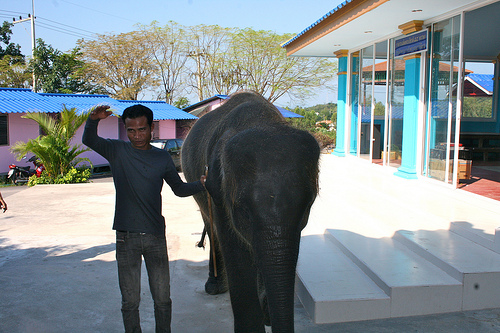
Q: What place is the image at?
A: It is at the pavement.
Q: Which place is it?
A: It is a pavement.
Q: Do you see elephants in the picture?
A: Yes, there is an elephant.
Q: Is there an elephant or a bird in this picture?
A: Yes, there is an elephant.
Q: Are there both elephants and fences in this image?
A: No, there is an elephant but no fences.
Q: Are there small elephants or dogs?
A: Yes, there is a small elephant.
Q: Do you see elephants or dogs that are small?
A: Yes, the elephant is small.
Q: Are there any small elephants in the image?
A: Yes, there is a small elephant.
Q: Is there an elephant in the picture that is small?
A: Yes, there is an elephant that is small.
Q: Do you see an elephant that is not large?
A: Yes, there is a small elephant.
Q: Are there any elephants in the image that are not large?
A: Yes, there is a small elephant.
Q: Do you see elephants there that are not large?
A: Yes, there is a small elephant.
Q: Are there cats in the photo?
A: No, there are no cats.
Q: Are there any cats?
A: No, there are no cats.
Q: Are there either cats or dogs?
A: No, there are no cats or dogs.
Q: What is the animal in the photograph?
A: The animal is an elephant.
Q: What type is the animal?
A: The animal is an elephant.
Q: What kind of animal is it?
A: The animal is an elephant.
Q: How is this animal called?
A: This is an elephant.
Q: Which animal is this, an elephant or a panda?
A: This is an elephant.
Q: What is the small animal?
A: The animal is an elephant.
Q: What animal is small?
A: The animal is an elephant.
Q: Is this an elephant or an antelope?
A: This is an elephant.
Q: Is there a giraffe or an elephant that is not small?
A: No, there is an elephant but it is small.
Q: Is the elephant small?
A: Yes, the elephant is small.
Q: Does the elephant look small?
A: Yes, the elephant is small.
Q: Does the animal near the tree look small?
A: Yes, the elephant is small.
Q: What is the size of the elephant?
A: The elephant is small.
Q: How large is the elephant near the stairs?
A: The elephant is small.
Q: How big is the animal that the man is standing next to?
A: The elephant is small.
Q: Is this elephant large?
A: No, the elephant is small.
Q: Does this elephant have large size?
A: No, the elephant is small.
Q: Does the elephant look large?
A: No, the elephant is small.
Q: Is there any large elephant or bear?
A: No, there is an elephant but it is small.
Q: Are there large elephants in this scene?
A: No, there is an elephant but it is small.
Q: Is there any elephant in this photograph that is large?
A: No, there is an elephant but it is small.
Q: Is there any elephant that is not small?
A: No, there is an elephant but it is small.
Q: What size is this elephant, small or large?
A: The elephant is small.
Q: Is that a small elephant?
A: Yes, that is a small elephant.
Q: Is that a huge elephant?
A: No, that is a small elephant.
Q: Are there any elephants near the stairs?
A: Yes, there is an elephant near the stairs.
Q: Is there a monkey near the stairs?
A: No, there is an elephant near the stairs.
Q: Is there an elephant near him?
A: Yes, there is an elephant near the man.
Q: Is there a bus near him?
A: No, there is an elephant near the man.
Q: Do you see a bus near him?
A: No, there is an elephant near the man.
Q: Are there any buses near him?
A: No, there is an elephant near the man.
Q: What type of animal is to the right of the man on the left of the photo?
A: The animal is an elephant.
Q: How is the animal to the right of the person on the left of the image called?
A: The animal is an elephant.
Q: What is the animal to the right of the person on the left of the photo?
A: The animal is an elephant.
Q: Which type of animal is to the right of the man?
A: The animal is an elephant.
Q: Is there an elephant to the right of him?
A: Yes, there is an elephant to the right of the man.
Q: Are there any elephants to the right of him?
A: Yes, there is an elephant to the right of the man.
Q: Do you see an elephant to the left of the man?
A: No, the elephant is to the right of the man.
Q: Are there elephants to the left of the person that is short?
A: No, the elephant is to the right of the man.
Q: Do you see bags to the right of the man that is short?
A: No, there is an elephant to the right of the man.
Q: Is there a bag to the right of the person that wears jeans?
A: No, there is an elephant to the right of the man.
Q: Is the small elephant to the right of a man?
A: Yes, the elephant is to the right of a man.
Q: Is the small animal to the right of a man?
A: Yes, the elephant is to the right of a man.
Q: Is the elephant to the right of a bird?
A: No, the elephant is to the right of a man.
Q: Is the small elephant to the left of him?
A: No, the elephant is to the right of the man.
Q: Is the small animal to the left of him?
A: No, the elephant is to the right of the man.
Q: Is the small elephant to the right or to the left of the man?
A: The elephant is to the right of the man.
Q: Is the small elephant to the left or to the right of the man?
A: The elephant is to the right of the man.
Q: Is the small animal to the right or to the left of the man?
A: The elephant is to the right of the man.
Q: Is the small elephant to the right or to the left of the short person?
A: The elephant is to the right of the man.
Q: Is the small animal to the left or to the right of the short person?
A: The elephant is to the right of the man.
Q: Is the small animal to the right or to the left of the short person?
A: The elephant is to the right of the man.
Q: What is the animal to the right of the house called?
A: The animal is an elephant.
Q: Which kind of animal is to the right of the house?
A: The animal is an elephant.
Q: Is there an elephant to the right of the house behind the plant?
A: Yes, there is an elephant to the right of the house.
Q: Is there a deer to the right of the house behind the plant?
A: No, there is an elephant to the right of the house.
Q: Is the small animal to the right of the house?
A: Yes, the elephant is to the right of the house.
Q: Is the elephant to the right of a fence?
A: No, the elephant is to the right of the house.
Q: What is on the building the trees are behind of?
A: The sign is on the building.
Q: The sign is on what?
A: The sign is on the building.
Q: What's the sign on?
A: The sign is on the building.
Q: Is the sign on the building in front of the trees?
A: Yes, the sign is on the building.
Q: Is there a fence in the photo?
A: No, there are no fences.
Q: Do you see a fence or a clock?
A: No, there are no fences or clocks.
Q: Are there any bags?
A: No, there are no bags.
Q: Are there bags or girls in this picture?
A: No, there are no bags or girls.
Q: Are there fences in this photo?
A: No, there are no fences.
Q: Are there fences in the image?
A: No, there are no fences.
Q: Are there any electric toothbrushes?
A: No, there are no electric toothbrushes.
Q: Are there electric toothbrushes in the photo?
A: No, there are no electric toothbrushes.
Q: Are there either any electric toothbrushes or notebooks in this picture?
A: No, there are no electric toothbrushes or notebooks.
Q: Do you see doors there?
A: Yes, there is a door.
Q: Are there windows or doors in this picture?
A: Yes, there is a door.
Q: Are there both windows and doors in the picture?
A: Yes, there are both a door and a window.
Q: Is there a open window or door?
A: Yes, there is an open door.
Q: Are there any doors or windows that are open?
A: Yes, the door is open.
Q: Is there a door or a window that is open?
A: Yes, the door is open.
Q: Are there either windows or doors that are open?
A: Yes, the door is open.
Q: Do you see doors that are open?
A: Yes, there is an open door.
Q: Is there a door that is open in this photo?
A: Yes, there is an open door.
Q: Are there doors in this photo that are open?
A: Yes, there is a door that is open.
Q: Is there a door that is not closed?
A: Yes, there is a open door.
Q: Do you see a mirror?
A: No, there are no mirrors.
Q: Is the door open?
A: Yes, the door is open.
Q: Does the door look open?
A: Yes, the door is open.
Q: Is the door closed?
A: No, the door is open.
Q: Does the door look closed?
A: No, the door is open.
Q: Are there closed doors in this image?
A: No, there is a door but it is open.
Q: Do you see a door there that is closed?
A: No, there is a door but it is open.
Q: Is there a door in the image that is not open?
A: No, there is a door but it is open.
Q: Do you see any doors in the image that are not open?
A: No, there is a door but it is open.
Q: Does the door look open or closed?
A: The door is open.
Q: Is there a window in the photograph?
A: Yes, there are windows.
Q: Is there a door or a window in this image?
A: Yes, there are windows.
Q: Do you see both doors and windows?
A: Yes, there are both windows and a door.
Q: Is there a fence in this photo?
A: No, there are no fences.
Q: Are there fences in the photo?
A: No, there are no fences.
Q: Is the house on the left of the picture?
A: Yes, the house is on the left of the image.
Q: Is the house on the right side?
A: No, the house is on the left of the image.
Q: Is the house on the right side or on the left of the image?
A: The house is on the left of the image.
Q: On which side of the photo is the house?
A: The house is on the left of the image.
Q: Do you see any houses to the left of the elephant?
A: Yes, there is a house to the left of the elephant.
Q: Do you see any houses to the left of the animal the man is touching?
A: Yes, there is a house to the left of the elephant.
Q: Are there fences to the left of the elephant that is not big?
A: No, there is a house to the left of the elephant.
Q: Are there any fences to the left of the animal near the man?
A: No, there is a house to the left of the elephant.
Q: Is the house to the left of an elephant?
A: Yes, the house is to the left of an elephant.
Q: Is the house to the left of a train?
A: No, the house is to the left of an elephant.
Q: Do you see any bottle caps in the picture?
A: No, there are no bottle caps.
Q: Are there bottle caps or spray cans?
A: No, there are no bottle caps or spray cans.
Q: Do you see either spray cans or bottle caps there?
A: No, there are no bottle caps or spray cans.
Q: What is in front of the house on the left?
A: The plant is in front of the house.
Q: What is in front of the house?
A: The plant is in front of the house.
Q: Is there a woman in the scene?
A: No, there are no women.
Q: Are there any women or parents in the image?
A: No, there are no women or parents.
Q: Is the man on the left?
A: Yes, the man is on the left of the image.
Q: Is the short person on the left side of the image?
A: Yes, the man is on the left of the image.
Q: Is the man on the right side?
A: No, the man is on the left of the image.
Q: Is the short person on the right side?
A: No, the man is on the left of the image.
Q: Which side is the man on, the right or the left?
A: The man is on the left of the image.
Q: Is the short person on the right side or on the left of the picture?
A: The man is on the left of the image.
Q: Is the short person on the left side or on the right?
A: The man is on the left of the image.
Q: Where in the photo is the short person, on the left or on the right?
A: The man is on the left of the image.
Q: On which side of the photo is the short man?
A: The man is on the left of the image.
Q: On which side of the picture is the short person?
A: The man is on the left of the image.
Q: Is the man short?
A: Yes, the man is short.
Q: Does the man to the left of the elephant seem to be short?
A: Yes, the man is short.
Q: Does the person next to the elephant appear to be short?
A: Yes, the man is short.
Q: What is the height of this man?
A: The man is short.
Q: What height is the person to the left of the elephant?
A: The man is short.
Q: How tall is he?
A: The man is short.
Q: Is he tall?
A: No, the man is short.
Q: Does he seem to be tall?
A: No, the man is short.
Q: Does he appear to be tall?
A: No, the man is short.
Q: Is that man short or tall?
A: The man is short.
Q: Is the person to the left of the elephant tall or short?
A: The man is short.